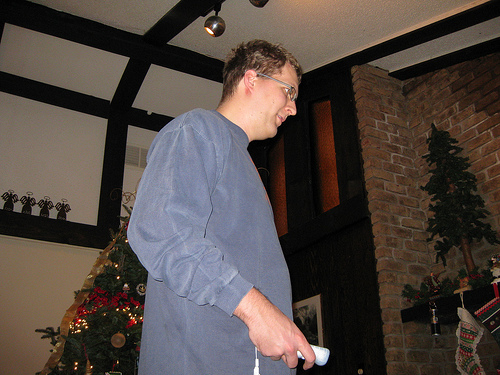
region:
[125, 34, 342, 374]
person holding a white remote control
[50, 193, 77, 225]
small angel shaped decoration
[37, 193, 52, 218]
small angel shaped decoration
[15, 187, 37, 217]
small angel shaped decoration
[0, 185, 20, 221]
small angel shaped decoration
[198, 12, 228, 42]
silver light mounted on the ceiling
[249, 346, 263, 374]
white tassel on a remote control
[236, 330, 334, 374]
white plastic remote control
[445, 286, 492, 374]
multicolored stocking hanging from the mantel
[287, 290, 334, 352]
white picture in a frame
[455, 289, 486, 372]
the stocking hanging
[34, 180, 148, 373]
the decorated Christmas tree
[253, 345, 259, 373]
the strap hanging from the wii controller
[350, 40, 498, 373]
the bricks on the walls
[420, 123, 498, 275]
the undecorated tree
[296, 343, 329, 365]
the wii controller in the man's hand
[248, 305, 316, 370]
the man's hand holding wii controller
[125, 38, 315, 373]
the man standing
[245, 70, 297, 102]
the glasses on the man's face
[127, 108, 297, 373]
the long sleeve shirt on the man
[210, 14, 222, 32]
a light on the ceiling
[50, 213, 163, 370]
a christmas gree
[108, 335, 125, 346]
an ornament on the christmas tree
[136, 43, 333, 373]
a man wearing glasses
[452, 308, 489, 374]
a stocking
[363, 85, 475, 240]
bricks on the wall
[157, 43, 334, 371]
a man in a blue shirt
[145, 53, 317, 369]
a man holding a white nintendo remote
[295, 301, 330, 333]
a picture on the wall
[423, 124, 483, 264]
a tree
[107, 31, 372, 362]
A man playing the Wii.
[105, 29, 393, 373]
A man using a Wii controller.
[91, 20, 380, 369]
the man is holding a remote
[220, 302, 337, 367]
the remote is white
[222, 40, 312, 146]
the man is wearing glasses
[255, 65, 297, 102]
the eye is open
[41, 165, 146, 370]
a christmas tree in the background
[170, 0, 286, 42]
lights on the ceiling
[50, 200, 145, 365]
the christmas lights are on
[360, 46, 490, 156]
the wall is made of bricks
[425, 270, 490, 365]
a stocking is hanging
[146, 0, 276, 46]
the lights are on